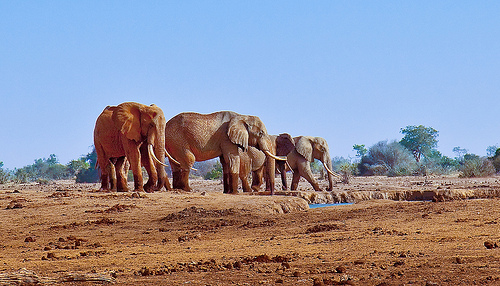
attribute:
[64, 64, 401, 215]
elephants — large, Three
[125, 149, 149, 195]
leg — wet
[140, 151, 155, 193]
leg — wet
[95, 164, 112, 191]
leg — wet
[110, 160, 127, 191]
leg — wet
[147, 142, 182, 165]
tusks — large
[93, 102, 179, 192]
elephant — large, gray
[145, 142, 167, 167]
tusk — ivory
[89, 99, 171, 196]
elephant — brown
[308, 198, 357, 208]
water — small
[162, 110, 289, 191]
elephant — large, gray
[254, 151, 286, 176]
tusk — white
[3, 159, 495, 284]
dirt — brown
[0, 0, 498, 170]
sky — clear, blue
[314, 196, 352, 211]
water — small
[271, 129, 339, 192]
elephant — large, gray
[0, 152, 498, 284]
desert — arid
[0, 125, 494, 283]
savanna — dirt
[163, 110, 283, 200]
elephant — brown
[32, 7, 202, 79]
sky — cloudless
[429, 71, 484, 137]
cloud — white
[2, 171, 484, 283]
ground — dirt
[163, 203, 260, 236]
pile — small